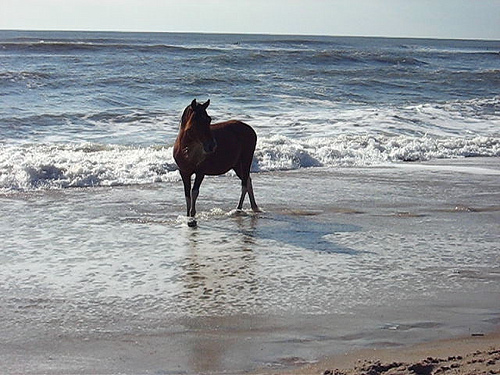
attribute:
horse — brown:
[167, 99, 267, 253]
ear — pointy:
[199, 90, 215, 112]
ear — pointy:
[188, 90, 199, 114]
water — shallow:
[144, 255, 282, 293]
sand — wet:
[404, 324, 475, 364]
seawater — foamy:
[22, 128, 106, 200]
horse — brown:
[152, 65, 261, 235]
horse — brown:
[170, 72, 274, 253]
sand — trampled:
[326, 324, 398, 355]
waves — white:
[287, 103, 377, 174]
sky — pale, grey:
[317, 3, 357, 53]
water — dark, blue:
[293, 69, 385, 129]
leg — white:
[228, 169, 268, 211]